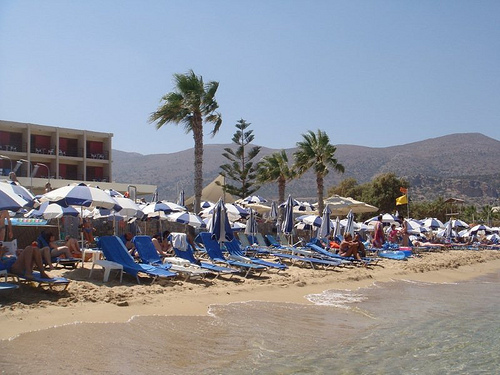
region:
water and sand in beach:
[9, 191, 489, 366]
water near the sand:
[215, 315, 479, 362]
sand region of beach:
[7, 293, 199, 317]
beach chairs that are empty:
[94, 220, 339, 273]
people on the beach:
[339, 221, 416, 256]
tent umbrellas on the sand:
[36, 183, 196, 231]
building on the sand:
[1, 109, 136, 184]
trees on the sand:
[156, 75, 333, 220]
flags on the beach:
[383, 186, 418, 219]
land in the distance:
[123, 138, 498, 192]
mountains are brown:
[108, 123, 498, 196]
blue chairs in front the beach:
[94, 223, 482, 335]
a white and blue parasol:
[42, 177, 124, 210]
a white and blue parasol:
[165, 206, 207, 228]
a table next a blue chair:
[85, 252, 130, 282]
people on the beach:
[0, 219, 102, 293]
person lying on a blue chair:
[37, 226, 82, 268]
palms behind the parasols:
[157, 65, 344, 196]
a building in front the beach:
[0, 110, 202, 360]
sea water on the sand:
[105, 272, 473, 369]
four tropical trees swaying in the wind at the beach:
[156, 70, 361, 197]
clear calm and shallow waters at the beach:
[215, 307, 497, 372]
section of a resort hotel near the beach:
[6, 115, 123, 184]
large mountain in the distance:
[346, 118, 495, 187]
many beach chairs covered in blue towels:
[107, 234, 321, 281]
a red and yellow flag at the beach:
[393, 184, 415, 236]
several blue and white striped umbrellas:
[45, 177, 297, 232]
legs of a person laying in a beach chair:
[14, 244, 51, 280]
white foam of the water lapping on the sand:
[305, 284, 364, 307]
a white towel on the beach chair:
[167, 232, 192, 251]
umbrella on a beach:
[28, 180, 131, 216]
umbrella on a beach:
[150, 190, 191, 222]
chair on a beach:
[126, 230, 178, 281]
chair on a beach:
[196, 227, 246, 275]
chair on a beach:
[251, 228, 288, 259]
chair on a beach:
[261, 230, 336, 262]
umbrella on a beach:
[415, 205, 450, 240]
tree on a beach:
[290, 120, 350, 185]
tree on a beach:
[155, 70, 220, 145]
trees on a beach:
[229, 121, 265, 191]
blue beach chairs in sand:
[94, 223, 167, 283]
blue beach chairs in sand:
[178, 230, 228, 266]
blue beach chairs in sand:
[229, 231, 302, 280]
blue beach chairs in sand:
[256, 219, 329, 274]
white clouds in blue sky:
[29, 25, 92, 91]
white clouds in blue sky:
[55, 42, 112, 100]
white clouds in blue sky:
[380, 53, 427, 110]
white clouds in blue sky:
[323, 36, 388, 82]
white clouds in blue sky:
[251, 34, 309, 70]